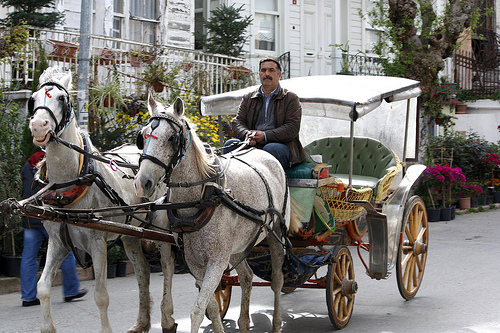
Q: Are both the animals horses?
A: Yes, all the animals are horses.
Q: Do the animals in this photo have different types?
A: No, all the animals are horses.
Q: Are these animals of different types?
A: No, all the animals are horses.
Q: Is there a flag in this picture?
A: No, there are no flags.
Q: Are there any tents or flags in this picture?
A: No, there are no flags or tents.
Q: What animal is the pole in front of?
A: The pole is in front of the horse.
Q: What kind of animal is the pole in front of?
A: The pole is in front of the horse.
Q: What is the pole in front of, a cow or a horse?
A: The pole is in front of a horse.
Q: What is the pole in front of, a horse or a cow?
A: The pole is in front of a horse.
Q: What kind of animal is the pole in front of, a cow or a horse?
A: The pole is in front of a horse.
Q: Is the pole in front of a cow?
A: No, the pole is in front of the horse.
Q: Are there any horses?
A: Yes, there is a horse.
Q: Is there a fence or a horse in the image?
A: Yes, there is a horse.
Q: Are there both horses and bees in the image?
A: No, there is a horse but no bees.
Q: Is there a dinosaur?
A: No, there are no dinosaurs.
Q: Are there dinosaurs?
A: No, there are no dinosaurs.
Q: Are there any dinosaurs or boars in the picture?
A: No, there are no dinosaurs or boars.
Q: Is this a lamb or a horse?
A: This is a horse.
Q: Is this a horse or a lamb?
A: This is a horse.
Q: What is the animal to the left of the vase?
A: The animal is a horse.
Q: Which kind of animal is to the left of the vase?
A: The animal is a horse.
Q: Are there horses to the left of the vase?
A: Yes, there is a horse to the left of the vase.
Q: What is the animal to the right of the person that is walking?
A: The animal is a horse.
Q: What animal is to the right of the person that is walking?
A: The animal is a horse.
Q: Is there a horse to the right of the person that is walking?
A: Yes, there is a horse to the right of the person.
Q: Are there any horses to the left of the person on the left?
A: No, the horse is to the right of the person.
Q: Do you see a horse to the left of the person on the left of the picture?
A: No, the horse is to the right of the person.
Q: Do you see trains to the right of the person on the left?
A: No, there is a horse to the right of the person.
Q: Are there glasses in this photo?
A: No, there are no glasses.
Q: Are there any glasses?
A: No, there are no glasses.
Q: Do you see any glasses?
A: No, there are no glasses.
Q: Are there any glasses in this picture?
A: No, there are no glasses.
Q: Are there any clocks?
A: No, there are no clocks.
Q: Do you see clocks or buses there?
A: No, there are no clocks or buses.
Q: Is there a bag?
A: No, there are no bags.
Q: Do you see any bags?
A: No, there are no bags.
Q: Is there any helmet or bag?
A: No, there are no bags or helmets.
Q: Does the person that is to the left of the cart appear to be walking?
A: Yes, the person is walking.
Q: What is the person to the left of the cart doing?
A: The person is walking.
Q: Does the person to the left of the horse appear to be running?
A: No, the person is walking.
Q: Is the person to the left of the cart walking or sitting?
A: The person is walking.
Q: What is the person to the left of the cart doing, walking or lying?
A: The person is walking.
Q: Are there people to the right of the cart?
A: No, the person is to the left of the cart.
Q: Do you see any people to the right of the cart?
A: No, the person is to the left of the cart.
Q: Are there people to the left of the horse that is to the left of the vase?
A: Yes, there is a person to the left of the horse.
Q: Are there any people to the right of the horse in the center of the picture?
A: No, the person is to the left of the horse.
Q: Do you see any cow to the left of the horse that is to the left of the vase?
A: No, there is a person to the left of the horse.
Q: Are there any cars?
A: No, there are no cars.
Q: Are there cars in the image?
A: No, there are no cars.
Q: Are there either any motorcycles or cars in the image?
A: No, there are no cars or motorcycles.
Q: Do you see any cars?
A: No, there are no cars.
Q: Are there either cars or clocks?
A: No, there are no cars or clocks.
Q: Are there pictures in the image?
A: No, there are no pictures.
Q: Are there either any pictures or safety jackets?
A: No, there are no pictures or safety jackets.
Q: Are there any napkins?
A: No, there are no napkins.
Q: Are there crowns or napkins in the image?
A: No, there are no napkins or crowns.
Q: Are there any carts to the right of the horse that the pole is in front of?
A: Yes, there is a cart to the right of the horse.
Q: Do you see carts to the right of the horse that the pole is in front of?
A: Yes, there is a cart to the right of the horse.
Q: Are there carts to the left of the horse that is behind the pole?
A: No, the cart is to the right of the horse.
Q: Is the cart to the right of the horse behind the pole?
A: Yes, the cart is to the right of the horse.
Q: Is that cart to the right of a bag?
A: No, the cart is to the right of the horse.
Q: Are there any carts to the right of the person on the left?
A: Yes, there is a cart to the right of the person.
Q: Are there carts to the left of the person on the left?
A: No, the cart is to the right of the person.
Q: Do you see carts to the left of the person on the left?
A: No, the cart is to the right of the person.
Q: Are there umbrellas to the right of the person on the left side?
A: No, there is a cart to the right of the person.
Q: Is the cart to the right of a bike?
A: No, the cart is to the right of a person.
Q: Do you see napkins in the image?
A: No, there are no napkins.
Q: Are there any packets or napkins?
A: No, there are no napkins or packets.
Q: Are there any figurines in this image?
A: No, there are no figurines.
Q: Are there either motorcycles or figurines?
A: No, there are no figurines or motorcycles.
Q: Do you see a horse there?
A: Yes, there is a horse.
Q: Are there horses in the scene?
A: Yes, there is a horse.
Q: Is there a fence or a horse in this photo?
A: Yes, there is a horse.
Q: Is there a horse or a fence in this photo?
A: Yes, there is a horse.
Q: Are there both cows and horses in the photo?
A: No, there is a horse but no cows.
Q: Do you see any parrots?
A: No, there are no parrots.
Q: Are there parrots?
A: No, there are no parrots.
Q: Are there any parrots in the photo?
A: No, there are no parrots.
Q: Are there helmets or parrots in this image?
A: No, there are no parrots or helmets.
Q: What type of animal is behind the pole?
A: The animal is a horse.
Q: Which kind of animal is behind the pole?
A: The animal is a horse.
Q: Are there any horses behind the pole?
A: Yes, there is a horse behind the pole.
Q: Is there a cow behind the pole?
A: No, there is a horse behind the pole.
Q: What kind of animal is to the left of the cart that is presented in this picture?
A: The animal is a horse.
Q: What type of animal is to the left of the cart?
A: The animal is a horse.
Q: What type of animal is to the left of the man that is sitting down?
A: The animal is a horse.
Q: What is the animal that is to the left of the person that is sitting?
A: The animal is a horse.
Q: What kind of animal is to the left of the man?
A: The animal is a horse.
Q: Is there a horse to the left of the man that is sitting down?
A: Yes, there is a horse to the left of the man.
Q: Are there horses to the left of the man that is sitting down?
A: Yes, there is a horse to the left of the man.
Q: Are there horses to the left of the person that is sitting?
A: Yes, there is a horse to the left of the man.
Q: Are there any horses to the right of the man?
A: No, the horse is to the left of the man.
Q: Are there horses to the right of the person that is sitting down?
A: No, the horse is to the left of the man.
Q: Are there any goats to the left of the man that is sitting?
A: No, there is a horse to the left of the man.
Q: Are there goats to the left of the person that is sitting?
A: No, there is a horse to the left of the man.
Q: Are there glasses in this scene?
A: No, there are no glasses.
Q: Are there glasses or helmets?
A: No, there are no glasses or helmets.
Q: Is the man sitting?
A: Yes, the man is sitting.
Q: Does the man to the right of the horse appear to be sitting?
A: Yes, the man is sitting.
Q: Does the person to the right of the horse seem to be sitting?
A: Yes, the man is sitting.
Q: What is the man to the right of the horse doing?
A: The man is sitting.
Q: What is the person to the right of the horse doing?
A: The man is sitting.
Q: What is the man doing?
A: The man is sitting.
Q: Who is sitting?
A: The man is sitting.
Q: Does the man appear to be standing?
A: No, the man is sitting.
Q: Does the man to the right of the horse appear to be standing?
A: No, the man is sitting.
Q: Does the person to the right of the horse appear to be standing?
A: No, the man is sitting.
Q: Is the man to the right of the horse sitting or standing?
A: The man is sitting.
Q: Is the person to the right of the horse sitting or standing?
A: The man is sitting.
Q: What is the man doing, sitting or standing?
A: The man is sitting.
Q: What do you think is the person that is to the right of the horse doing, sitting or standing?
A: The man is sitting.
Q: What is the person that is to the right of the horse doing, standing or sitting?
A: The man is sitting.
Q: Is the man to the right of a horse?
A: Yes, the man is to the right of a horse.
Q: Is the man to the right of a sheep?
A: No, the man is to the right of a horse.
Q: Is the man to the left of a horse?
A: No, the man is to the right of a horse.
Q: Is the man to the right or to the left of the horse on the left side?
A: The man is to the right of the horse.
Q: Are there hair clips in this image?
A: No, there are no hair clips.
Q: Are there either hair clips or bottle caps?
A: No, there are no hair clips or bottle caps.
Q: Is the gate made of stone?
A: No, the gate is made of iron.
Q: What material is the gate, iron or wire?
A: The gate is made of iron.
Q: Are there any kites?
A: No, there are no kites.